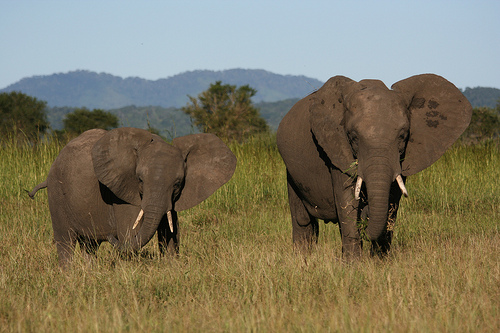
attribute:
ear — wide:
[173, 133, 237, 210]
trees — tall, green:
[5, 87, 499, 159]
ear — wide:
[90, 127, 162, 208]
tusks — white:
[391, 176, 411, 193]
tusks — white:
[355, 170, 362, 198]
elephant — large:
[287, 75, 495, 255]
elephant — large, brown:
[275, 71, 472, 263]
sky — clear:
[102, 14, 229, 44]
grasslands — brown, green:
[154, 274, 494, 323]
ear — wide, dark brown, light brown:
[391, 72, 473, 175]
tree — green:
[183, 47, 321, 174]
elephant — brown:
[42, 124, 234, 249]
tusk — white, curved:
[348, 177, 366, 205]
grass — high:
[138, 262, 421, 316]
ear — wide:
[305, 75, 361, 182]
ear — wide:
[302, 71, 361, 180]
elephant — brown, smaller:
[21, 124, 239, 265]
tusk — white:
[352, 176, 363, 202]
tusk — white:
[392, 173, 410, 197]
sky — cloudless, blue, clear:
[2, 3, 484, 91]